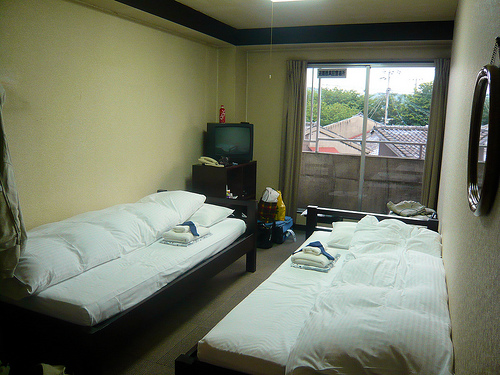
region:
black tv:
[178, 87, 266, 167]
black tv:
[205, 87, 250, 163]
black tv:
[172, 101, 309, 256]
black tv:
[201, 51, 295, 225]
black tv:
[151, 71, 279, 186]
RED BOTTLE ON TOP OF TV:
[214, 102, 259, 123]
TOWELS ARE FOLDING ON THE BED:
[295, 227, 337, 278]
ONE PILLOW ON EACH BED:
[321, 214, 384, 266]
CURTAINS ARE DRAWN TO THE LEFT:
[274, 52, 311, 219]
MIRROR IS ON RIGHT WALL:
[467, 62, 499, 228]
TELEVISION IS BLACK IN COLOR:
[201, 123, 271, 160]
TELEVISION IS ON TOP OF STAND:
[191, 157, 265, 204]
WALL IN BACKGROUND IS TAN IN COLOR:
[291, 147, 432, 220]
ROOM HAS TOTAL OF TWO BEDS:
[16, 182, 478, 362]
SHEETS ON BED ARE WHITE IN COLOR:
[186, 238, 451, 362]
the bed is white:
[332, 232, 388, 326]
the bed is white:
[321, 257, 347, 364]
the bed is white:
[300, 267, 330, 357]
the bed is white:
[285, 282, 337, 365]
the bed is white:
[265, 196, 311, 327]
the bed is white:
[266, 242, 342, 366]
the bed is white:
[237, 230, 300, 361]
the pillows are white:
[303, 289, 352, 366]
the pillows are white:
[318, 327, 356, 371]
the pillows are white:
[334, 335, 359, 367]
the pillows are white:
[341, 295, 358, 355]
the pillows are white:
[322, 306, 364, 358]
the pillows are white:
[369, 292, 398, 369]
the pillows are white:
[350, 289, 380, 368]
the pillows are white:
[339, 267, 362, 367]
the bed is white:
[256, 293, 297, 361]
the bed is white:
[271, 267, 326, 350]